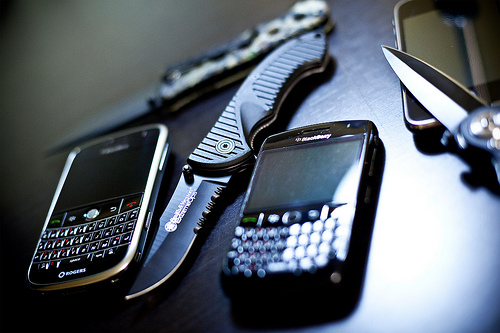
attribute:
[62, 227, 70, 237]
button — White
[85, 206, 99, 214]
button — White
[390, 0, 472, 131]
phone — touchscreen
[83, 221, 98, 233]
button — white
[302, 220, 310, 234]
button — white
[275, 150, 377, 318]
phone — blackberry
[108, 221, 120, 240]
button — White 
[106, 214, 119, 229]
button — white